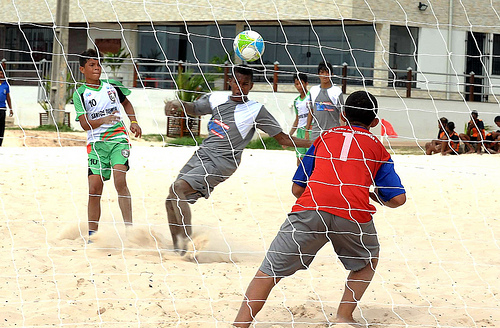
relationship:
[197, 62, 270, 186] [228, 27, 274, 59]
boy running after a ball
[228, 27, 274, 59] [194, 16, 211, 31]
ball flying in air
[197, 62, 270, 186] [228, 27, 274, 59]
boy waiting for ball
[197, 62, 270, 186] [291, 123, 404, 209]
boy in red and blue shirt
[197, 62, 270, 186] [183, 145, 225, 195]
boy wearing gray shorts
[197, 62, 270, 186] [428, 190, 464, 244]
boy standing in sand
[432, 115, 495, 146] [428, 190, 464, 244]
children sitting on sand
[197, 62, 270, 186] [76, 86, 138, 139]
boy wearing green shirt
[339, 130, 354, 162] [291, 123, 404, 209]
number on boys shirt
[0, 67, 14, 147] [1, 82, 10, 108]
man in blue shirt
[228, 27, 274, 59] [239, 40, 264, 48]
ball that colorful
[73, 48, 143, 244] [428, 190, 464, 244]
boy standing in sand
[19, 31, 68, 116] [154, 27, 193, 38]
net made of rope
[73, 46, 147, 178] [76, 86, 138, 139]
boy in green and white shirt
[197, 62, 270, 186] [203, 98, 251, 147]
boy wearing grey shirt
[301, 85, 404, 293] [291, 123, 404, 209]
boy wearing red and blue shirt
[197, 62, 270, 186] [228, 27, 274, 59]
boy about to catch ball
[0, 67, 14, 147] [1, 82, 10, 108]
man wearing blue shirt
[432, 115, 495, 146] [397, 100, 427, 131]
children sitting by wall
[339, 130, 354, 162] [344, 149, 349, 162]
number written in white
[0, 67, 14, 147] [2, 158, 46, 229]
man standing on beach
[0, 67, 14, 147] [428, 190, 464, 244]
man standing on sand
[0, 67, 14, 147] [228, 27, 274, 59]
man not playing with ball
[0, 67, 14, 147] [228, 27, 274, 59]
man standing near ball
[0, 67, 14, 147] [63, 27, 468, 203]
man watching game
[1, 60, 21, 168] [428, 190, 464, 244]
man standing on sand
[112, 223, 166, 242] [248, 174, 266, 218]
dust on ground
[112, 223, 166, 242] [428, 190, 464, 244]
dust on sand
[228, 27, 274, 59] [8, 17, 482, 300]
ball in photo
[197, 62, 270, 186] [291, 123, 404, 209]
boy wearing red and blue shirt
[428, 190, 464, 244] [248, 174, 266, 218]
sand on ground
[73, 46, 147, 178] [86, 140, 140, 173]
boy wearing green shorts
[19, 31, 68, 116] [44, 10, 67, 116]
net on goal post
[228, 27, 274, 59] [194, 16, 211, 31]
ball in air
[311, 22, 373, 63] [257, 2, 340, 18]
windows on building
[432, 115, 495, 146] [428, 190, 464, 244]
children seated on sand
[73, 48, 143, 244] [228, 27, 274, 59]
boy playing ball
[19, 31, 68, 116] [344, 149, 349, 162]
net that white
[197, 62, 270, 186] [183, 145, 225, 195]
boy wearing grey shorts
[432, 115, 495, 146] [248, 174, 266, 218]
children sitting on ground